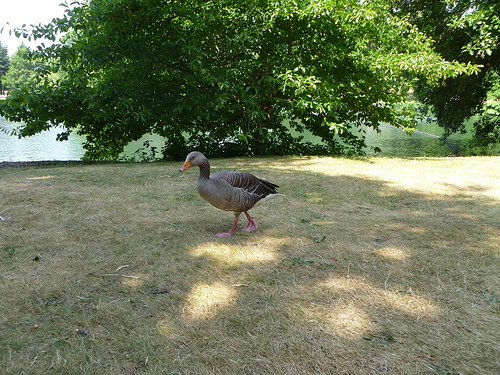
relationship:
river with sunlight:
[1, 112, 498, 162] [2, 104, 93, 158]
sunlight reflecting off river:
[2, 104, 93, 158] [0, 109, 500, 162]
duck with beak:
[180, 151, 281, 238] [178, 160, 189, 170]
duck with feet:
[167, 136, 289, 248] [208, 205, 285, 245]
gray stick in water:
[398, 125, 443, 140] [0, 114, 477, 164]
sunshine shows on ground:
[393, 157, 490, 205] [85, 271, 325, 336]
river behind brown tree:
[0, 109, 500, 162] [0, 1, 485, 154]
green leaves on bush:
[66, 0, 500, 163] [17, 12, 452, 150]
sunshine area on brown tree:
[281, 5, 483, 127] [0, 1, 485, 154]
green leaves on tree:
[66, 0, 500, 163] [0, 0, 487, 160]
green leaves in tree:
[66, 0, 500, 163] [0, 0, 487, 160]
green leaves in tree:
[66, 0, 500, 163] [2, 1, 469, 185]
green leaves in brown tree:
[215, 12, 381, 120] [253, 92, 282, 112]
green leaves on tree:
[66, 0, 500, 163] [18, 11, 430, 154]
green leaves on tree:
[66, 0, 500, 163] [207, 8, 299, 155]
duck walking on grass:
[180, 151, 281, 238] [216, 248, 296, 296]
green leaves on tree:
[66, 0, 500, 163] [252, 17, 434, 131]